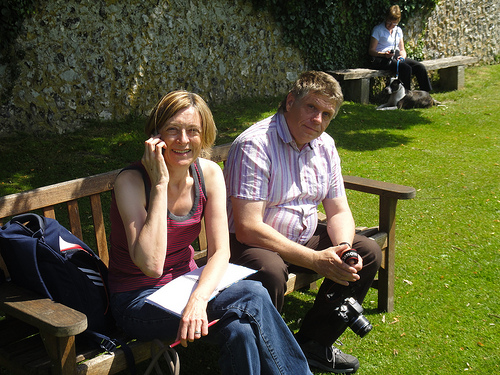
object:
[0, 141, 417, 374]
bench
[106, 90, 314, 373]
people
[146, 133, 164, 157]
cell phone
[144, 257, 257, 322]
book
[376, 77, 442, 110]
dog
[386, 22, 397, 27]
glasses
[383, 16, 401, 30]
woman's face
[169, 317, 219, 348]
pencil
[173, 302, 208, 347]
hand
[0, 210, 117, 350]
back pack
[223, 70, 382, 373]
man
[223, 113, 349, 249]
shirt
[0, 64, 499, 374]
grass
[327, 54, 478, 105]
bench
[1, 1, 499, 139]
wall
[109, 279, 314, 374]
jeans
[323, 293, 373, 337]
camera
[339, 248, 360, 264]
strap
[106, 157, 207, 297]
tank top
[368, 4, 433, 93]
person